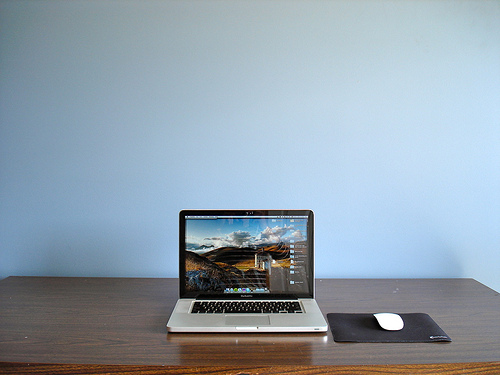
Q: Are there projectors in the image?
A: No, there are no projectors.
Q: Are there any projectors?
A: No, there are no projectors.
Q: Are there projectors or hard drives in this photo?
A: No, there are no projectors or hard drives.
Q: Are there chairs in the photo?
A: No, there are no chairs.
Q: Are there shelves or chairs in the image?
A: No, there are no chairs or shelves.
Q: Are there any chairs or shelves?
A: No, there are no chairs or shelves.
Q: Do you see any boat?
A: No, there are no boats.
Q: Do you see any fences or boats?
A: No, there are no boats or fences.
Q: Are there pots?
A: No, there are no pots.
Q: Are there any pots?
A: No, there are no pots.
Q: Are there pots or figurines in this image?
A: No, there are no pots or figurines.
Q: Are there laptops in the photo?
A: Yes, there is a laptop.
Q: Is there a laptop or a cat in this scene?
A: Yes, there is a laptop.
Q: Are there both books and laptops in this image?
A: No, there is a laptop but no books.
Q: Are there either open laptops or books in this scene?
A: Yes, there is an open laptop.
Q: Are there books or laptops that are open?
A: Yes, the laptop is open.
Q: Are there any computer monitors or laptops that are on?
A: Yes, the laptop is on.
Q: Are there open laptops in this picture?
A: Yes, there is an open laptop.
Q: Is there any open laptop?
A: Yes, there is an open laptop.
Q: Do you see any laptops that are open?
A: Yes, there is an open laptop.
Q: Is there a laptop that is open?
A: Yes, there is a laptop that is open.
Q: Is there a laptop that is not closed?
A: Yes, there is a open laptop.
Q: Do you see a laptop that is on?
A: Yes, there is a laptop that is on.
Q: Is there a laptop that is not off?
A: Yes, there is a laptop that is on.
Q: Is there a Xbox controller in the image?
A: No, there are no Xbox controllers.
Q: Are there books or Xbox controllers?
A: No, there are no Xbox controllers or books.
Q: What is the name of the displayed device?
A: The device is a laptop.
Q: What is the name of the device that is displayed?
A: The device is a laptop.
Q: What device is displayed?
A: The device is a laptop.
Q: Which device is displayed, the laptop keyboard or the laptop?
A: The laptop is displayed.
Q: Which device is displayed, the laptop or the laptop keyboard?
A: The laptop is displayed.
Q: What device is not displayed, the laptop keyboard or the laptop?
A: The keyboard is not displayed.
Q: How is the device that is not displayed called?
A: The device is a keyboard.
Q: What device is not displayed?
A: The device is a keyboard.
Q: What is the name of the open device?
A: The device is a laptop.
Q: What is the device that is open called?
A: The device is a laptop.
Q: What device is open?
A: The device is a laptop.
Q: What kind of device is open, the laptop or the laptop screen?
A: The laptop is open.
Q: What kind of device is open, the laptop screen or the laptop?
A: The laptop is open.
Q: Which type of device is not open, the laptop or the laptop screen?
A: The screen is not open.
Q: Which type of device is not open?
A: The device is a screen.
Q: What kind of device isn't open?
A: The device is a screen.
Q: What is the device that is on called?
A: The device is a laptop.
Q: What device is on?
A: The device is a laptop.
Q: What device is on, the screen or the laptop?
A: The laptop is on.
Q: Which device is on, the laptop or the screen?
A: The laptop is on.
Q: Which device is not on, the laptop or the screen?
A: The screen is not on.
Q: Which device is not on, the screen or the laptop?
A: The screen is not on.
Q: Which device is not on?
A: The device is a screen.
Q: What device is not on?
A: The device is a screen.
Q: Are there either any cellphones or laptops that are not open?
A: No, there is a laptop but it is open.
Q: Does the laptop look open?
A: Yes, the laptop is open.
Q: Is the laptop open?
A: Yes, the laptop is open.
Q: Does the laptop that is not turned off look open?
A: Yes, the laptop is open.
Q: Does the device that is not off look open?
A: Yes, the laptop is open.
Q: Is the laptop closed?
A: No, the laptop is open.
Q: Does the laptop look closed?
A: No, the laptop is open.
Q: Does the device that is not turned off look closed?
A: No, the laptop is open.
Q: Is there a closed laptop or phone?
A: No, there is a laptop but it is open.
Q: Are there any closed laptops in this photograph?
A: No, there is a laptop but it is open.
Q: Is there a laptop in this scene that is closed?
A: No, there is a laptop but it is open.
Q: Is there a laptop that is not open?
A: No, there is a laptop but it is open.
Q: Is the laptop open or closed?
A: The laptop is open.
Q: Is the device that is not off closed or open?
A: The laptop is open.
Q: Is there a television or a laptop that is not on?
A: No, there is a laptop but it is on.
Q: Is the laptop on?
A: Yes, the laptop is on.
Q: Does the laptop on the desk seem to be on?
A: Yes, the laptop computer is on.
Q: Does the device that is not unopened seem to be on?
A: Yes, the laptop computer is on.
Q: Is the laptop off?
A: No, the laptop is on.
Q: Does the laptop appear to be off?
A: No, the laptop is on.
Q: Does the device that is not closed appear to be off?
A: No, the laptop is on.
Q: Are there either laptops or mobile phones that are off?
A: No, there is a laptop but it is on.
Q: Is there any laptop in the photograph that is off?
A: No, there is a laptop but it is on.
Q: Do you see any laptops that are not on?
A: No, there is a laptop but it is on.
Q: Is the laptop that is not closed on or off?
A: The laptop is on.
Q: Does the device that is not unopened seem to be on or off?
A: The laptop is on.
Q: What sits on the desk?
A: The laptop sits on the desk.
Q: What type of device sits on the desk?
A: The device is a laptop.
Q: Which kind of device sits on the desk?
A: The device is a laptop.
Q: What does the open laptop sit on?
A: The laptop sits on the desk.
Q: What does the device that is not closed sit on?
A: The laptop sits on the desk.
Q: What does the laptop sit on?
A: The laptop sits on the desk.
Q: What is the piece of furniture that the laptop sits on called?
A: The piece of furniture is a desk.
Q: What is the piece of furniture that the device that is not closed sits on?
A: The piece of furniture is a desk.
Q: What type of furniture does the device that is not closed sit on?
A: The laptop sits on the desk.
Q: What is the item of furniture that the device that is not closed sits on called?
A: The piece of furniture is a desk.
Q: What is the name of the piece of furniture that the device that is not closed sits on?
A: The piece of furniture is a desk.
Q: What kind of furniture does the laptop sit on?
A: The laptop sits on the desk.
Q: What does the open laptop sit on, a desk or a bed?
A: The laptop computer sits on a desk.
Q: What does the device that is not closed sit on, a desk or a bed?
A: The laptop computer sits on a desk.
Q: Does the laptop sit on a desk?
A: Yes, the laptop sits on a desk.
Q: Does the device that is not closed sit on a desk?
A: Yes, the laptop sits on a desk.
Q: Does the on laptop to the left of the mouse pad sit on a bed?
A: No, the laptop computer sits on a desk.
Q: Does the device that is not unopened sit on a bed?
A: No, the laptop computer sits on a desk.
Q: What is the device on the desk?
A: The device is a laptop.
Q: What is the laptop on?
A: The laptop is on the desk.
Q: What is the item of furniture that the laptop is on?
A: The piece of furniture is a desk.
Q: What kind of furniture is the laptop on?
A: The laptop is on the desk.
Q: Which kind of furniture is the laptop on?
A: The laptop is on the desk.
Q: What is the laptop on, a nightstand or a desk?
A: The laptop is on a desk.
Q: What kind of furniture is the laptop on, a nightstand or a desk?
A: The laptop is on a desk.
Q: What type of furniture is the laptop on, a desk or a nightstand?
A: The laptop is on a desk.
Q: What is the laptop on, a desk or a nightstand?
A: The laptop is on a desk.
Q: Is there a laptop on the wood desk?
A: Yes, there is a laptop on the desk.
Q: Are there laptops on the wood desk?
A: Yes, there is a laptop on the desk.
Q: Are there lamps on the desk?
A: No, there is a laptop on the desk.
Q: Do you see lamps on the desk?
A: No, there is a laptop on the desk.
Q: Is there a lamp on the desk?
A: No, there is a laptop on the desk.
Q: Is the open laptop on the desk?
A: Yes, the laptop is on the desk.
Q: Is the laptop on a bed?
A: No, the laptop is on the desk.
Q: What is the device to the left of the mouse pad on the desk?
A: The device is a laptop.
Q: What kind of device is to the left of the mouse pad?
A: The device is a laptop.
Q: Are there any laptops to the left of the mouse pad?
A: Yes, there is a laptop to the left of the mouse pad.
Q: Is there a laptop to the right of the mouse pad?
A: No, the laptop is to the left of the mouse pad.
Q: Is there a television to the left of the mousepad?
A: No, there is a laptop to the left of the mousepad.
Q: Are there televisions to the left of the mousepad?
A: No, there is a laptop to the left of the mousepad.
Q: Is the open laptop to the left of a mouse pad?
A: Yes, the laptop is to the left of a mouse pad.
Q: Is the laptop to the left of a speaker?
A: No, the laptop is to the left of a mouse pad.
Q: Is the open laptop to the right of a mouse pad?
A: No, the laptop is to the left of a mouse pad.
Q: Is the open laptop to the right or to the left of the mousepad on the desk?
A: The laptop is to the left of the mousepad.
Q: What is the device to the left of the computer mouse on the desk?
A: The device is a laptop.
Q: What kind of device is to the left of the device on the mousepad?
A: The device is a laptop.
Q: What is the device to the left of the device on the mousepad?
A: The device is a laptop.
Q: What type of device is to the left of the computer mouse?
A: The device is a laptop.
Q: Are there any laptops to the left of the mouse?
A: Yes, there is a laptop to the left of the mouse.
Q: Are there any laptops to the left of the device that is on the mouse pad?
A: Yes, there is a laptop to the left of the mouse.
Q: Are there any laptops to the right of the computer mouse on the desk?
A: No, the laptop is to the left of the mouse.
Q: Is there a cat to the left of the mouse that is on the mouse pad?
A: No, there is a laptop to the left of the computer mouse.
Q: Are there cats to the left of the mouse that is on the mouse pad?
A: No, there is a laptop to the left of the computer mouse.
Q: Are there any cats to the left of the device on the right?
A: No, there is a laptop to the left of the computer mouse.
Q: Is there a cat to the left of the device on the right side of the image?
A: No, there is a laptop to the left of the computer mouse.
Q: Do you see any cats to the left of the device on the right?
A: No, there is a laptop to the left of the computer mouse.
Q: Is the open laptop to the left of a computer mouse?
A: Yes, the laptop is to the left of a computer mouse.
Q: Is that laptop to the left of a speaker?
A: No, the laptop is to the left of a computer mouse.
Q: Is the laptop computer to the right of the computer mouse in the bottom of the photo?
A: No, the laptop computer is to the left of the computer mouse.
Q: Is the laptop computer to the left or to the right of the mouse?
A: The laptop computer is to the left of the mouse.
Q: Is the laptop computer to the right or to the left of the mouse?
A: The laptop computer is to the left of the mouse.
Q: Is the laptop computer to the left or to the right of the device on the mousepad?
A: The laptop computer is to the left of the mouse.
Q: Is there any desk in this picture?
A: Yes, there is a desk.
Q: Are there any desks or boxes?
A: Yes, there is a desk.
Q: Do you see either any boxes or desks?
A: Yes, there is a desk.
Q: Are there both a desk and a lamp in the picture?
A: No, there is a desk but no lamps.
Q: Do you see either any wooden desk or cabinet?
A: Yes, there is a wood desk.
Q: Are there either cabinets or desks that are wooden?
A: Yes, the desk is wooden.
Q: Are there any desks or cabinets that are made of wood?
A: Yes, the desk is made of wood.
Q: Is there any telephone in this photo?
A: No, there are no phones.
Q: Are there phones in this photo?
A: No, there are no phones.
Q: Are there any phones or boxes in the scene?
A: No, there are no phones or boxes.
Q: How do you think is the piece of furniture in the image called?
A: The piece of furniture is a desk.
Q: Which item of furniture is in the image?
A: The piece of furniture is a desk.